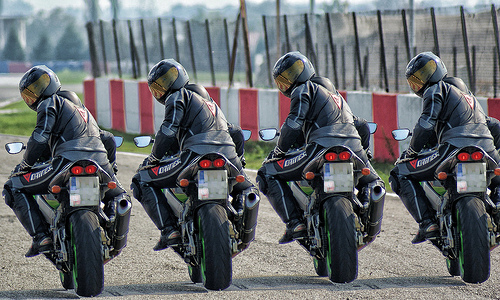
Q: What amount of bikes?
A: Four.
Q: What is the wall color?
A: Red.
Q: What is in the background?
A: Fence.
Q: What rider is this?
A: Left.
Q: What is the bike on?
A: Dirt road.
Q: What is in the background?
A: Grass.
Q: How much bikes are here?
A: Four.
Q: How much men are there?
A: Four.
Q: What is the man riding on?
A: Bike.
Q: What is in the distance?
A: Fence.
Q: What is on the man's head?
A: Helmet.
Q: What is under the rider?
A: Bike.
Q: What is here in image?
A: Group of motorcyclists.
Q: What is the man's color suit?
A: Black.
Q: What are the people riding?
A: Motorcycles.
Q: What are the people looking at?
A: The camera.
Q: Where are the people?
A: Track.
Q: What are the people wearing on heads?
A: Helmets.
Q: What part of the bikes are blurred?
A: License plates.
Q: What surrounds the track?
A: Fence.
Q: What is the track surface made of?
A: Dirt.